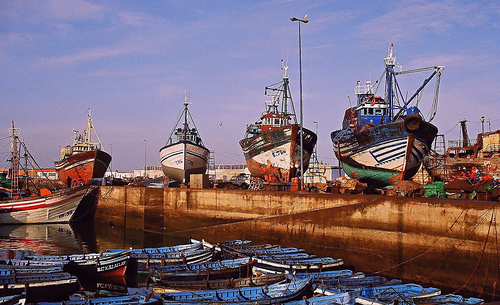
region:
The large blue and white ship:
[323, 48, 446, 192]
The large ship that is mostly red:
[37, 105, 109, 184]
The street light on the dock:
[286, 8, 315, 193]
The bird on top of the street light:
[298, 11, 311, 23]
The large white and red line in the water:
[0, 120, 88, 227]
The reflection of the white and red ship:
[0, 221, 85, 258]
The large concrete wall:
[90, 183, 499, 298]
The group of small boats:
[0, 238, 485, 304]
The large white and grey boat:
[151, 84, 209, 184]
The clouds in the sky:
[0, 0, 497, 166]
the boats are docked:
[32, 87, 314, 259]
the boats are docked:
[117, 117, 381, 236]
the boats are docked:
[133, 66, 427, 292]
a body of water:
[3, 217, 432, 249]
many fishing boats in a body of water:
[0, 216, 498, 301]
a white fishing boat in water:
[159, 280, 314, 304]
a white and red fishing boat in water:
[0, 198, 92, 225]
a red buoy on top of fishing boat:
[36, 185, 59, 203]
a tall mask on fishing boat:
[4, 115, 40, 197]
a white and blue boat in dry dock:
[331, 42, 466, 192]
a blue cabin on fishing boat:
[352, 87, 390, 121]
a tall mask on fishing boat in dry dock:
[383, 35, 441, 120]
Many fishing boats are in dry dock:
[58, 55, 499, 190]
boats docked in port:
[155, 81, 462, 231]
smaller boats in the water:
[149, 227, 361, 299]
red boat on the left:
[50, 108, 115, 195]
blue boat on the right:
[335, 51, 446, 198]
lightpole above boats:
[284, 6, 314, 203]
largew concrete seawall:
[188, 189, 493, 269]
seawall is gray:
[212, 188, 495, 273]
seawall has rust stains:
[126, 189, 280, 239]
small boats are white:
[139, 247, 359, 297]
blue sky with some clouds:
[15, 5, 252, 80]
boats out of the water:
[91, 53, 478, 228]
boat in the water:
[7, 102, 137, 270]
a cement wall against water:
[108, 147, 292, 264]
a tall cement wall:
[152, 150, 369, 300]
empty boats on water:
[29, 224, 304, 303]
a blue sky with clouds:
[54, 10, 317, 151]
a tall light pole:
[268, 3, 353, 203]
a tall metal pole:
[271, 6, 366, 218]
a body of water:
[109, 227, 146, 253]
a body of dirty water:
[102, 230, 137, 246]